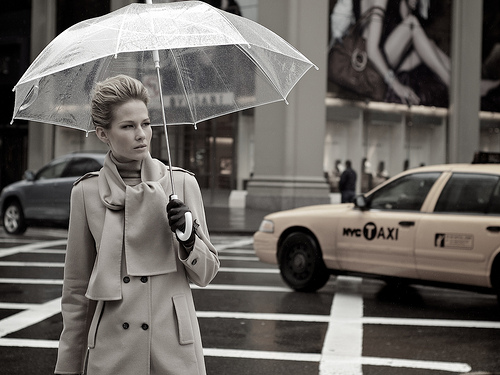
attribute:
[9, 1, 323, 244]
umbrella — white, large, open, clear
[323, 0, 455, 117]
picture — large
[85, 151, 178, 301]
scarf — neutral colored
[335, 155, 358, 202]
person — standing up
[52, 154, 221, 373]
coat — buttoned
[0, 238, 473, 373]
lines — white, painted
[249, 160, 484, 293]
cab — taxi